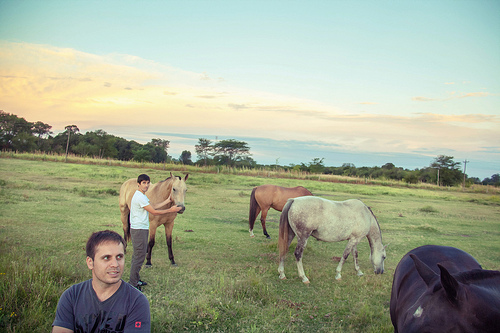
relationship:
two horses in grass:
[232, 173, 393, 298] [2, 178, 499, 332]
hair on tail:
[240, 186, 261, 237] [231, 184, 263, 224]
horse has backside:
[386, 243, 499, 333] [253, 182, 263, 205]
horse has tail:
[386, 243, 499, 333] [244, 187, 262, 230]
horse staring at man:
[386, 243, 499, 333] [48, 227, 153, 333]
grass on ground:
[0, 147, 500, 333] [87, 143, 476, 331]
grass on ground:
[0, 147, 500, 333] [437, 211, 497, 240]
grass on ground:
[0, 147, 500, 333] [2, 147, 499, 327]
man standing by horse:
[48, 227, 153, 333] [118, 170, 188, 264]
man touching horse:
[48, 227, 153, 333] [116, 169, 196, 270]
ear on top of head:
[406, 251, 440, 291] [399, 276, 474, 331]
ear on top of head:
[429, 259, 466, 306] [399, 276, 474, 331]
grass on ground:
[37, 134, 474, 210] [356, 167, 498, 269]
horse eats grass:
[270, 192, 390, 284] [0, 147, 500, 333]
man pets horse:
[128, 172, 184, 291] [116, 169, 196, 270]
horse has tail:
[270, 192, 390, 284] [274, 197, 298, 259]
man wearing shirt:
[48, 227, 153, 333] [52, 276, 150, 331]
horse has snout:
[386, 243, 499, 333] [373, 265, 385, 272]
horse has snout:
[386, 243, 499, 333] [319, 220, 331, 229]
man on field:
[48, 227, 153, 333] [1, 145, 486, 325]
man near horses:
[48, 227, 153, 333] [98, 161, 403, 293]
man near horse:
[48, 227, 153, 333] [171, 166, 411, 267]